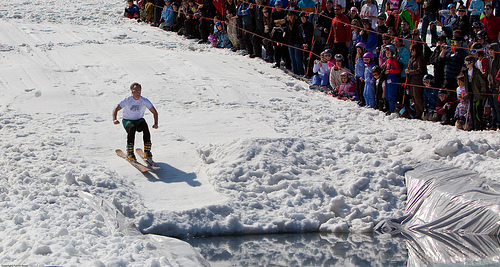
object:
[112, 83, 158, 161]
man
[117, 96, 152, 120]
shirt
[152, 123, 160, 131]
hands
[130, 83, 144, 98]
head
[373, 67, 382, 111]
person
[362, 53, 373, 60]
helmet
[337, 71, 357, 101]
person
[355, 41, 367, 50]
helmet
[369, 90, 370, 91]
blue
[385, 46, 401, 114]
person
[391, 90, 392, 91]
blue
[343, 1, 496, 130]
crowd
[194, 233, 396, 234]
edge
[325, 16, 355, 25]
rope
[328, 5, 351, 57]
person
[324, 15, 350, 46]
shirt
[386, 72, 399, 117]
pants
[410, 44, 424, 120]
person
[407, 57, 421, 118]
clothes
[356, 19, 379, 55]
person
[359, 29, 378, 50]
jacket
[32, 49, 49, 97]
lines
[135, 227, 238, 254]
hole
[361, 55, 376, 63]
head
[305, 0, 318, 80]
lines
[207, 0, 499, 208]
side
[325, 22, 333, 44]
long sleeves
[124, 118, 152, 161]
ski pants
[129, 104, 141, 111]
logo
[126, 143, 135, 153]
lines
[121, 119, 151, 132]
shorts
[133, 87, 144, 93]
goggles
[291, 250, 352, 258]
water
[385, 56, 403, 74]
shirt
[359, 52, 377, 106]
child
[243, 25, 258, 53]
pants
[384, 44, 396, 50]
helmet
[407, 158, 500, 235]
tarp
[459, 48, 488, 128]
people